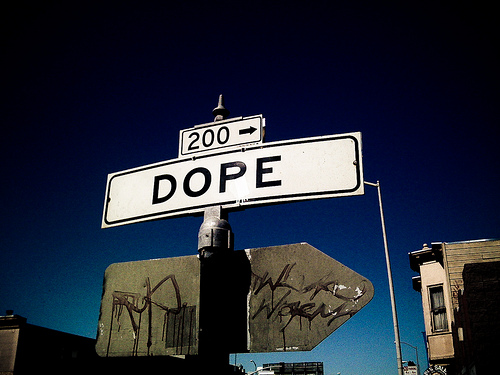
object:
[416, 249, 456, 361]
extended room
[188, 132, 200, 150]
lettering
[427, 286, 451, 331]
window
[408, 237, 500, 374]
house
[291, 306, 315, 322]
ink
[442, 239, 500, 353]
planks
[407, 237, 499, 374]
building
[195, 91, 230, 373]
pole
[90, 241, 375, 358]
sign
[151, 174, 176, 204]
black letter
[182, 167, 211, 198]
black letter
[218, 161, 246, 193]
black letter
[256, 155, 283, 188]
black letter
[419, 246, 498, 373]
fence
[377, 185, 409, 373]
lamp pole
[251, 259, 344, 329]
graffiti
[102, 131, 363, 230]
sign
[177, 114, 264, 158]
signs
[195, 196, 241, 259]
pole topper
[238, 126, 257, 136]
arrow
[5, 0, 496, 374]
sky